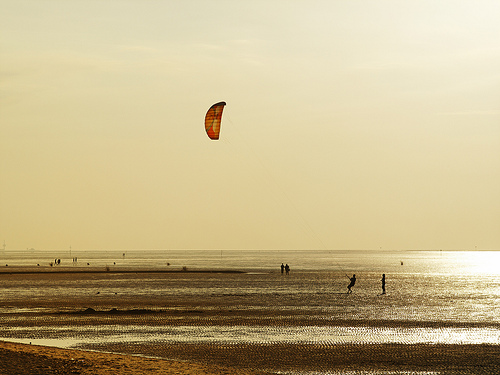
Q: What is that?
A: A kite.